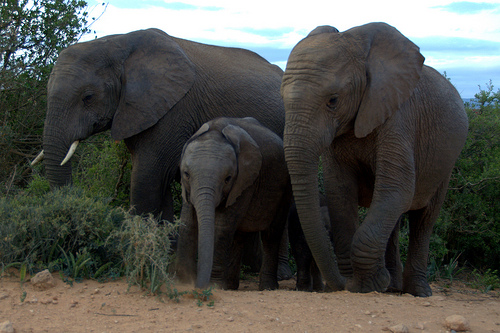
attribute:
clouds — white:
[90, 5, 499, 52]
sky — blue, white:
[1, 0, 498, 114]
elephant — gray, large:
[280, 21, 467, 296]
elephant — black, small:
[286, 35, 455, 217]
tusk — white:
[29, 150, 43, 166]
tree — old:
[14, 71, 29, 153]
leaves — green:
[0, 0, 107, 152]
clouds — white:
[72, 1, 498, 48]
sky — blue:
[0, 1, 497, 103]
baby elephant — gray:
[172, 117, 315, 294]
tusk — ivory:
[24, 145, 51, 169]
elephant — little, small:
[180, 113, 291, 285]